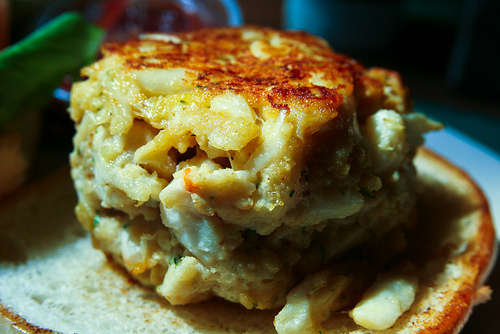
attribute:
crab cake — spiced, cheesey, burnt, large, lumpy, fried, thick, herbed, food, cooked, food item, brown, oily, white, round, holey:
[64, 21, 446, 333]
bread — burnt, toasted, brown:
[0, 144, 495, 333]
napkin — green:
[0, 8, 105, 128]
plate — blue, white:
[2, 109, 499, 332]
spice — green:
[180, 98, 186, 104]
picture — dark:
[1, 1, 500, 333]